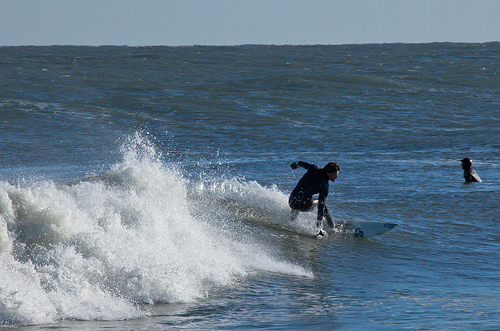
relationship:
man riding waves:
[288, 160, 344, 240] [1, 124, 292, 326]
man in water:
[288, 160, 344, 240] [2, 43, 497, 330]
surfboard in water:
[333, 211, 400, 243] [2, 43, 497, 330]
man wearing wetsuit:
[288, 160, 344, 240] [284, 171, 341, 208]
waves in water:
[1, 130, 317, 328] [2, 43, 497, 330]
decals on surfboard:
[344, 217, 403, 243] [301, 209, 413, 247]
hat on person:
[459, 158, 472, 169] [453, 147, 488, 189]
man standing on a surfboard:
[288, 160, 344, 240] [279, 218, 397, 245]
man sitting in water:
[462, 154, 481, 184] [2, 43, 497, 330]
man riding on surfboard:
[288, 160, 344, 240] [290, 216, 401, 243]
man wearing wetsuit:
[284, 151, 342, 221] [296, 160, 327, 215]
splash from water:
[102, 133, 294, 227] [2, 43, 497, 330]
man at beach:
[288, 160, 344, 240] [1, 33, 493, 325]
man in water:
[288, 160, 344, 240] [138, 104, 393, 274]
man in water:
[459, 157, 483, 185] [2, 43, 497, 330]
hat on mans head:
[460, 157, 472, 165] [460, 158, 472, 169]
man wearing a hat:
[459, 157, 483, 185] [460, 157, 472, 165]